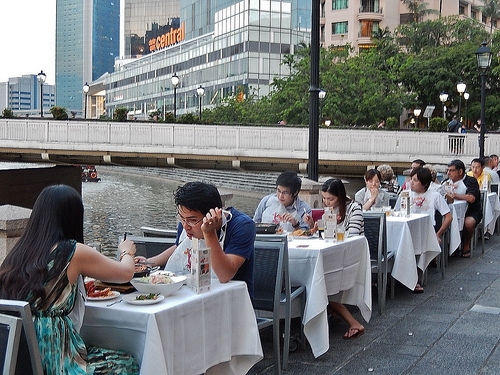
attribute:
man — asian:
[128, 172, 261, 309]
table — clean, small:
[71, 258, 270, 374]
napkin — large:
[166, 240, 224, 284]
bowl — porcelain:
[127, 266, 191, 300]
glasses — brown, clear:
[168, 207, 206, 231]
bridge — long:
[3, 111, 493, 169]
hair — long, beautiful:
[2, 179, 101, 324]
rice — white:
[135, 267, 177, 287]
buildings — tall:
[5, 1, 476, 109]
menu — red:
[310, 203, 327, 225]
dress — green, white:
[6, 236, 143, 374]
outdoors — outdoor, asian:
[12, 146, 500, 368]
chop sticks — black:
[118, 228, 130, 246]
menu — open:
[183, 239, 216, 301]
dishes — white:
[120, 271, 196, 312]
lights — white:
[394, 47, 497, 133]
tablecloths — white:
[81, 185, 497, 372]